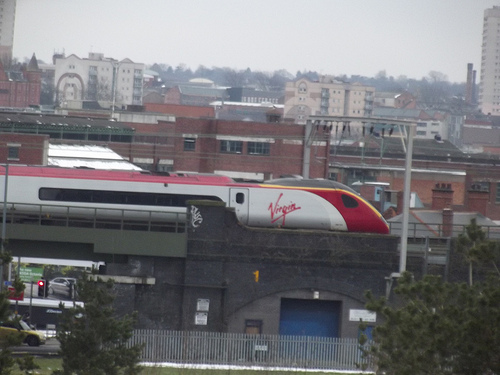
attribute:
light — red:
[33, 279, 45, 289]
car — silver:
[46, 275, 93, 299]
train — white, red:
[1, 158, 393, 233]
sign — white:
[195, 296, 210, 311]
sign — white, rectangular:
[344, 308, 379, 324]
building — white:
[44, 52, 159, 113]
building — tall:
[478, 4, 498, 119]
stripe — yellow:
[253, 177, 353, 193]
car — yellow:
[1, 312, 47, 348]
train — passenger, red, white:
[55, 145, 415, 285]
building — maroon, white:
[43, 44, 150, 104]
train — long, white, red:
[2, 149, 416, 251]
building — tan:
[279, 77, 380, 123]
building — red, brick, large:
[0, 107, 332, 187]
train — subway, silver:
[3, 153, 396, 248]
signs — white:
[193, 287, 219, 330]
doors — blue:
[275, 294, 343, 368]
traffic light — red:
[33, 272, 50, 299]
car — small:
[4, 321, 48, 348]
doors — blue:
[281, 297, 344, 367]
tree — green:
[55, 277, 130, 368]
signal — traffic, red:
[27, 273, 46, 288]